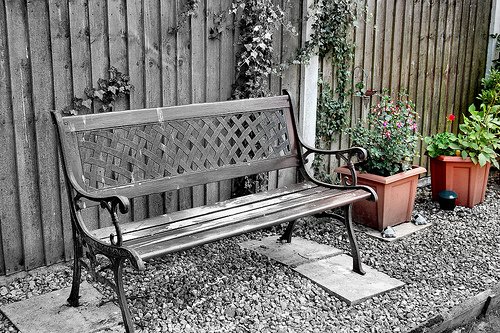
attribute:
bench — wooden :
[48, 88, 385, 329]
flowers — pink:
[369, 98, 420, 140]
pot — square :
[333, 160, 425, 228]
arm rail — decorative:
[287, 97, 375, 190]